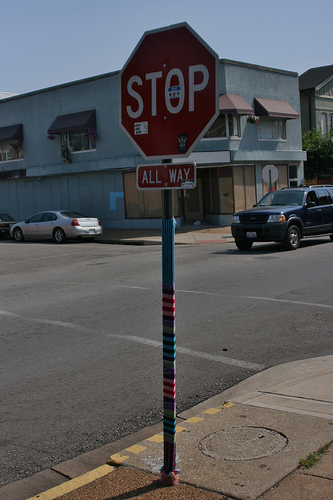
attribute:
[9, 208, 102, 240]
car — stopped, silver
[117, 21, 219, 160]
stop sign — red, octagonal, tall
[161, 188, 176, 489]
post — round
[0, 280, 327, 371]
crosswalk — faded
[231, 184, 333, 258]
suv — stopped, blue, moving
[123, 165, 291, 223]
window — boarded, boarded up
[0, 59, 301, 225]
building — blue, abandoned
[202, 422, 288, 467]
cap — round, gray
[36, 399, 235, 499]
curb — yellow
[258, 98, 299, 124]
awning — red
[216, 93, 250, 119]
awning — red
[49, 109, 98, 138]
awning — red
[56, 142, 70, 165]
plants — green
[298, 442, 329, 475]
weeds — yellowed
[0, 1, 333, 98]
sky — clear